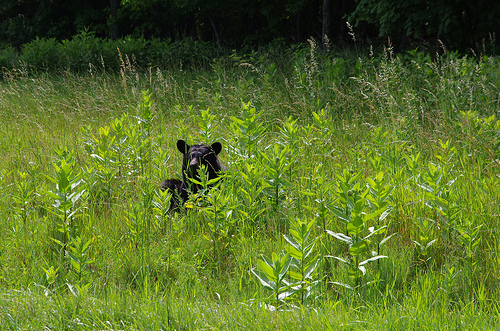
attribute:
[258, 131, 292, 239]
plant — small and green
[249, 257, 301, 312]
green plant — small and green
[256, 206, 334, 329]
plant — small and green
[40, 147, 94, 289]
plant — green 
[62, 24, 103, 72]
plant — small and green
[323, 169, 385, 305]
green plant — small and green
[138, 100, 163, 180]
green — small and green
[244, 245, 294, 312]
plant — small and green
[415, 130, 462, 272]
plants — small and green